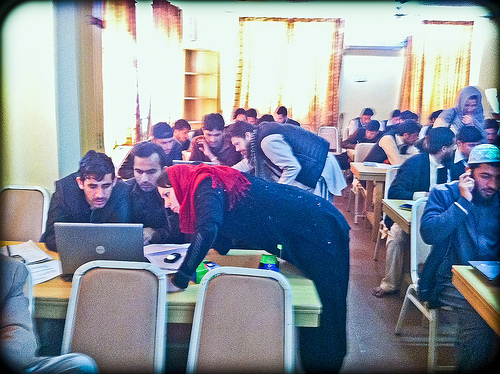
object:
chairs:
[70, 256, 323, 364]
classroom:
[2, 3, 497, 372]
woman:
[154, 160, 342, 275]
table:
[15, 294, 316, 325]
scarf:
[162, 161, 231, 222]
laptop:
[50, 216, 145, 257]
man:
[426, 146, 491, 254]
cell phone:
[455, 161, 474, 187]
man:
[244, 122, 342, 194]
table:
[132, 174, 306, 186]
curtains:
[240, 20, 335, 111]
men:
[69, 149, 164, 213]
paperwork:
[15, 237, 46, 270]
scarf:
[446, 79, 484, 123]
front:
[9, 254, 498, 367]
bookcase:
[173, 42, 268, 54]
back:
[72, 0, 137, 13]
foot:
[369, 282, 399, 305]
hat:
[465, 140, 496, 163]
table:
[355, 152, 383, 179]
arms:
[386, 141, 425, 154]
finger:
[458, 170, 474, 193]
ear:
[462, 158, 469, 177]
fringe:
[226, 181, 252, 200]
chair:
[191, 266, 295, 369]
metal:
[231, 263, 275, 281]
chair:
[74, 259, 169, 370]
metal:
[113, 257, 138, 270]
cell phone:
[164, 247, 177, 266]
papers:
[153, 236, 185, 269]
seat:
[214, 294, 268, 370]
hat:
[149, 123, 172, 135]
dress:
[206, 178, 347, 281]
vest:
[255, 121, 329, 190]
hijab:
[324, 163, 342, 193]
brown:
[225, 302, 253, 360]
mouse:
[164, 245, 179, 264]